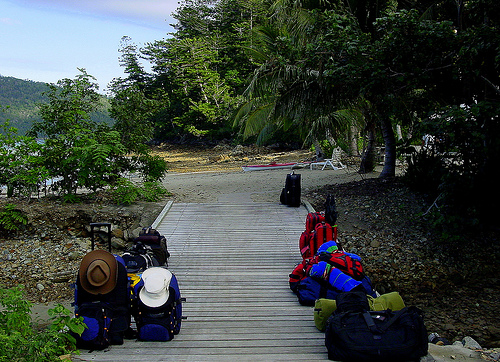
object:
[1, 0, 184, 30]
clouds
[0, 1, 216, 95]
sky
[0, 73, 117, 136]
hill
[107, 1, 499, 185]
tree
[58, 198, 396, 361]
sidewalk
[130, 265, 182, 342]
bag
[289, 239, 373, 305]
luggage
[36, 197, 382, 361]
walkways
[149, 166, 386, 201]
beach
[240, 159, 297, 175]
canoe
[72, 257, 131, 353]
backpack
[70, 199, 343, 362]
bridge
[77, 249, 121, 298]
hat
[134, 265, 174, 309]
hat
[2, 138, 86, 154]
water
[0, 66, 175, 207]
trees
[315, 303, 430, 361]
bag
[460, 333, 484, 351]
rocks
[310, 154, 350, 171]
chair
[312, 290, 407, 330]
roll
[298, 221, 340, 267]
bag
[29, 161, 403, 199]
sand